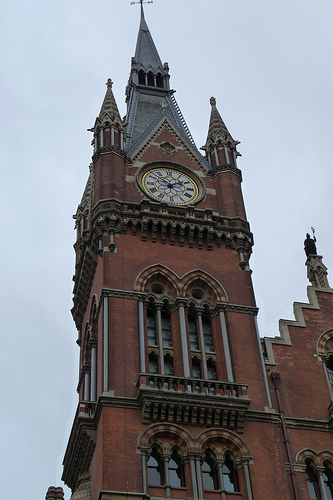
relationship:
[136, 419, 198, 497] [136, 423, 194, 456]
window with arch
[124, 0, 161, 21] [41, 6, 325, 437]
cross at top of building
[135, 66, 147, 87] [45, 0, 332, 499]
opening in building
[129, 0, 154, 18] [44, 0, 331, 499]
cross on top of church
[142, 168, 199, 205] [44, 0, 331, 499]
clock on top of church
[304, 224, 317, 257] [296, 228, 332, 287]
statue on roof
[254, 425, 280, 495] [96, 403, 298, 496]
bricks in wall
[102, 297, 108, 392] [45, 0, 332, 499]
column on building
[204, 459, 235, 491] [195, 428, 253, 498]
reflection in window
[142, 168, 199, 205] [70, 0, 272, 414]
clock on tower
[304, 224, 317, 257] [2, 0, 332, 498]
statue on top o f building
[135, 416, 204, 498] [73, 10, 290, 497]
window on tower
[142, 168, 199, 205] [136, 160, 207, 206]
clock has accents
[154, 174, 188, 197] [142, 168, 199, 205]
circle inside clock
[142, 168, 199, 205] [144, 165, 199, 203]
clock with accents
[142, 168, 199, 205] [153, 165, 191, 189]
clock with numerals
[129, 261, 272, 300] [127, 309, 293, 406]
arches over windows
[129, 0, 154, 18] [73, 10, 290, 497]
cross at top of tower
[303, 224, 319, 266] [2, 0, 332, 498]
statue on top of building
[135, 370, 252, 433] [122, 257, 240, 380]
balcony below window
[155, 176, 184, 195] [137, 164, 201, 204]
dials on front of clock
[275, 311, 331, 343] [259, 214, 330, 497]
chipping paint on building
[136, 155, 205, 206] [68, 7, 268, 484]
clock in tower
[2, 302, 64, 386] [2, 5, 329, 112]
clouds in blue sky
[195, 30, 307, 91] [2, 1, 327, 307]
clouds in sky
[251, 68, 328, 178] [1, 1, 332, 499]
clouds in sky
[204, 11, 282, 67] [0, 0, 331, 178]
clouds in sky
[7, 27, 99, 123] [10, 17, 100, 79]
clouds in sky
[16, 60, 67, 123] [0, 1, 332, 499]
clouds in blue sky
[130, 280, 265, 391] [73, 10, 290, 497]
window on tower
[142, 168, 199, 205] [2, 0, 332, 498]
clock on building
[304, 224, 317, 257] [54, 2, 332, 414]
statue on roof top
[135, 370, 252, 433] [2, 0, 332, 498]
balcony on edge of a building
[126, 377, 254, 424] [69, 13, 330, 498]
balcony on tower